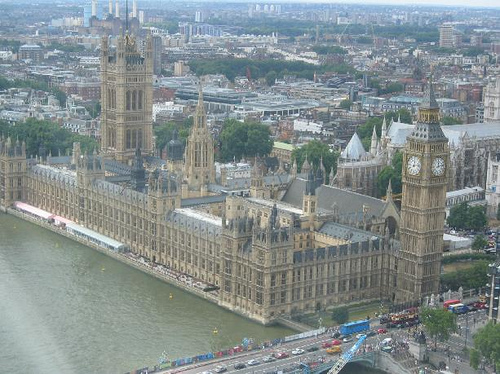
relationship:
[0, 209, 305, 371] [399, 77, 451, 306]
water next to clock tower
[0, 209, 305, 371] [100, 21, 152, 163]
water next to tower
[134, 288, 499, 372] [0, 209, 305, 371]
highway by water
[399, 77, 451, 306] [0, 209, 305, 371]
clock tower by water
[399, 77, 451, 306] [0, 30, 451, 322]
clock tower connected to building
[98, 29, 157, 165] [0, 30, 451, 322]
tower connected to building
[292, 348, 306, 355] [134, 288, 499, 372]
car on highway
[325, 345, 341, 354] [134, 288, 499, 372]
car on highway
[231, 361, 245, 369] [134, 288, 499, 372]
car on highway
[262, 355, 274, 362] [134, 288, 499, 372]
car on highway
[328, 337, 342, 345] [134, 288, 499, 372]
car on highway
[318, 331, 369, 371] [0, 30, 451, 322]
crane in front of building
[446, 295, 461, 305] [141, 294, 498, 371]
bus on highway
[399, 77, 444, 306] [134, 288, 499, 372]
clock tower by highway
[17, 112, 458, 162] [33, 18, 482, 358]
trees in city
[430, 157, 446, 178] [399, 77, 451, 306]
clock on clock tower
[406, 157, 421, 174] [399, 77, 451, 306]
clock on clock tower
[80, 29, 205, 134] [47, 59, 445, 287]
tower of building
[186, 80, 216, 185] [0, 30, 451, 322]
tower on top of building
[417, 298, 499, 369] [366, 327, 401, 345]
trees on side of road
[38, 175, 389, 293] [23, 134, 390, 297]
windows on side of building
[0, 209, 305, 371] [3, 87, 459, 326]
water next to building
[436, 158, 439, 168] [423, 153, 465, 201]
hand on clock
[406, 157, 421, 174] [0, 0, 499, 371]
clock in photo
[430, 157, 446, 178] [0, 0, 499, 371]
clock in photo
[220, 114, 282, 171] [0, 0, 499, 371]
trees in photo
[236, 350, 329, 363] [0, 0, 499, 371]
cars in photo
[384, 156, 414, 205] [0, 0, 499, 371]
ground in photo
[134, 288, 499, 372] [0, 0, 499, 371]
highway in photo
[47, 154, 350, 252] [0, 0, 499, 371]
rooftop in photo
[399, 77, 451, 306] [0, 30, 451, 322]
clock tower right side of building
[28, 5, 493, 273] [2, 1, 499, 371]
buildings in city